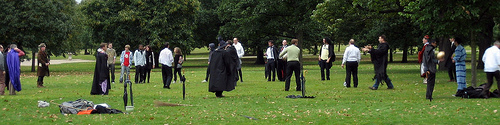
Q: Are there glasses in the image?
A: No, there are no glasses.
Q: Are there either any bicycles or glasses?
A: No, there are no glasses or bicycles.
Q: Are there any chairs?
A: No, there are no chairs.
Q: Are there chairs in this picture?
A: No, there are no chairs.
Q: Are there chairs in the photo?
A: No, there are no chairs.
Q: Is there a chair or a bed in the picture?
A: No, there are no chairs or beds.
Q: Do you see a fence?
A: No, there are no fences.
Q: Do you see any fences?
A: No, there are no fences.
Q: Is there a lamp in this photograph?
A: No, there are no lamps.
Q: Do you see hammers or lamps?
A: No, there are no lamps or hammers.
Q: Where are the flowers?
A: The flowers are on the grass.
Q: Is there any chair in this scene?
A: No, there are no chairs.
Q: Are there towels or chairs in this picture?
A: No, there are no chairs or towels.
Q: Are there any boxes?
A: No, there are no boxes.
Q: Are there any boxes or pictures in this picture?
A: No, there are no boxes or pictures.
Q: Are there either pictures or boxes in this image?
A: No, there are no boxes or pictures.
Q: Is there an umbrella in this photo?
A: Yes, there is an umbrella.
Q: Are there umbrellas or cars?
A: Yes, there is an umbrella.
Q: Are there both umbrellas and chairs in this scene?
A: No, there is an umbrella but no chairs.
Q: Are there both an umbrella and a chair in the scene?
A: No, there is an umbrella but no chairs.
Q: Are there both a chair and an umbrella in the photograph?
A: No, there is an umbrella but no chairs.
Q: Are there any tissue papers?
A: No, there are no tissue papers.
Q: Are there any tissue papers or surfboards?
A: No, there are no tissue papers or surfboards.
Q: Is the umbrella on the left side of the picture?
A: Yes, the umbrella is on the left of the image.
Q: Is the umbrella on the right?
A: No, the umbrella is on the left of the image.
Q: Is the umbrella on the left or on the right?
A: The umbrella is on the left of the image.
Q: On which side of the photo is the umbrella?
A: The umbrella is on the left of the image.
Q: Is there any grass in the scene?
A: Yes, there is grass.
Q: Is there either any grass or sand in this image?
A: Yes, there is grass.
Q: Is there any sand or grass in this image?
A: Yes, there is grass.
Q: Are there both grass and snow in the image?
A: No, there is grass but no snow.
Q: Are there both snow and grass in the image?
A: No, there is grass but no snow.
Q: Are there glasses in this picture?
A: No, there are no glasses.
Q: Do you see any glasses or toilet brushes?
A: No, there are no glasses or toilet brushes.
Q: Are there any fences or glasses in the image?
A: No, there are no fences or glasses.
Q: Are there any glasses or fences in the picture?
A: No, there are no fences or glasses.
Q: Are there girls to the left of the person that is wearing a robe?
A: Yes, there is a girl to the left of the person.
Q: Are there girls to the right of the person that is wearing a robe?
A: No, the girl is to the left of the person.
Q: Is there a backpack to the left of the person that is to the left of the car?
A: No, there is a girl to the left of the person.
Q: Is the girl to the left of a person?
A: Yes, the girl is to the left of a person.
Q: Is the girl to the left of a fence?
A: No, the girl is to the left of a person.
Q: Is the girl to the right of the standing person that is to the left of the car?
A: No, the girl is to the left of the person.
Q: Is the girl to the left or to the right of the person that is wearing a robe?
A: The girl is to the left of the person.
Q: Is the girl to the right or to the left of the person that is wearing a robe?
A: The girl is to the left of the person.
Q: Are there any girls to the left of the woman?
A: Yes, there is a girl to the left of the woman.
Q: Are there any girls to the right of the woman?
A: No, the girl is to the left of the woman.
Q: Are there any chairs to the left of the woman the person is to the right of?
A: No, there is a girl to the left of the woman.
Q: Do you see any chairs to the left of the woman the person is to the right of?
A: No, there is a girl to the left of the woman.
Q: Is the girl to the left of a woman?
A: Yes, the girl is to the left of a woman.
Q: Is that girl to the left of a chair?
A: No, the girl is to the left of a woman.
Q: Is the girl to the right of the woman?
A: No, the girl is to the left of the woman.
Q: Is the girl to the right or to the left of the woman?
A: The girl is to the left of the woman.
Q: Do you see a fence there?
A: No, there are no fences.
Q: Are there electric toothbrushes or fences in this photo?
A: No, there are no fences or electric toothbrushes.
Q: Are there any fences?
A: No, there are no fences.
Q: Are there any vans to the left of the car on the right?
A: No, there is a person to the left of the car.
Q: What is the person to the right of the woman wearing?
A: The person is wearing a robe.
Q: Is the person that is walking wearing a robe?
A: Yes, the person is wearing a robe.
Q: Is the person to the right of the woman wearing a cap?
A: No, the person is wearing a robe.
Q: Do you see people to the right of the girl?
A: Yes, there is a person to the right of the girl.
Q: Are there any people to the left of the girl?
A: No, the person is to the right of the girl.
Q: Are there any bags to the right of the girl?
A: No, there is a person to the right of the girl.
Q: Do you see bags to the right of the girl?
A: No, there is a person to the right of the girl.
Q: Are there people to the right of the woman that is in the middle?
A: Yes, there is a person to the right of the woman.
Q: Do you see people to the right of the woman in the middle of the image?
A: Yes, there is a person to the right of the woman.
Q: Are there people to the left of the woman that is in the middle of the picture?
A: No, the person is to the right of the woman.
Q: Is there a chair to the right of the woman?
A: No, there is a person to the right of the woman.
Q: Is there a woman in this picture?
A: Yes, there is a woman.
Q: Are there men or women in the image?
A: Yes, there is a woman.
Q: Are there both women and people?
A: Yes, there are both a woman and a person.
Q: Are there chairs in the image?
A: No, there are no chairs.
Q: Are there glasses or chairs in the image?
A: No, there are no chairs or glasses.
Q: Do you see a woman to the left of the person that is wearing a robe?
A: Yes, there is a woman to the left of the person.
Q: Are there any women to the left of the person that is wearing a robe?
A: Yes, there is a woman to the left of the person.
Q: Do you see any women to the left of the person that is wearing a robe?
A: Yes, there is a woman to the left of the person.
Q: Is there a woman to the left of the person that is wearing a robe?
A: Yes, there is a woman to the left of the person.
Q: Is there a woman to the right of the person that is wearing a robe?
A: No, the woman is to the left of the person.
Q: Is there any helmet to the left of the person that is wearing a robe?
A: No, there is a woman to the left of the person.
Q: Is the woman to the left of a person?
A: Yes, the woman is to the left of a person.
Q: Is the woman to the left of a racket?
A: No, the woman is to the left of a person.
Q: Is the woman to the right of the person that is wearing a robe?
A: No, the woman is to the left of the person.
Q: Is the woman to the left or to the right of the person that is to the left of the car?
A: The woman is to the left of the person.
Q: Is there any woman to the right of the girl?
A: Yes, there is a woman to the right of the girl.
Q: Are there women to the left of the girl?
A: No, the woman is to the right of the girl.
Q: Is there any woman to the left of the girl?
A: No, the woman is to the right of the girl.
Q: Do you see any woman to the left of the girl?
A: No, the woman is to the right of the girl.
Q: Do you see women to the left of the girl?
A: No, the woman is to the right of the girl.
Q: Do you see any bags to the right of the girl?
A: No, there is a woman to the right of the girl.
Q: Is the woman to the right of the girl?
A: Yes, the woman is to the right of the girl.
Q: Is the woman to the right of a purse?
A: No, the woman is to the right of the girl.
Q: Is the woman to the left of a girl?
A: No, the woman is to the right of a girl.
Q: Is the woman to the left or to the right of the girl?
A: The woman is to the right of the girl.